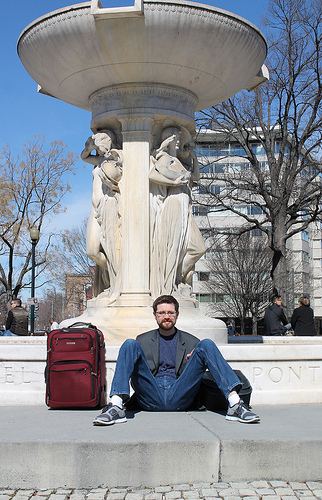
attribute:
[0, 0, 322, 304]
sky — blue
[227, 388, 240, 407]
sock — white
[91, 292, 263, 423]
man — light-skinned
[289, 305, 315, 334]
coat — black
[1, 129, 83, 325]
tree — pictured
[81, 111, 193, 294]
monument — pictured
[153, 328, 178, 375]
shirt — white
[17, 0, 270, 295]
monument — white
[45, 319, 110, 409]
bag — pictured, red, luggage